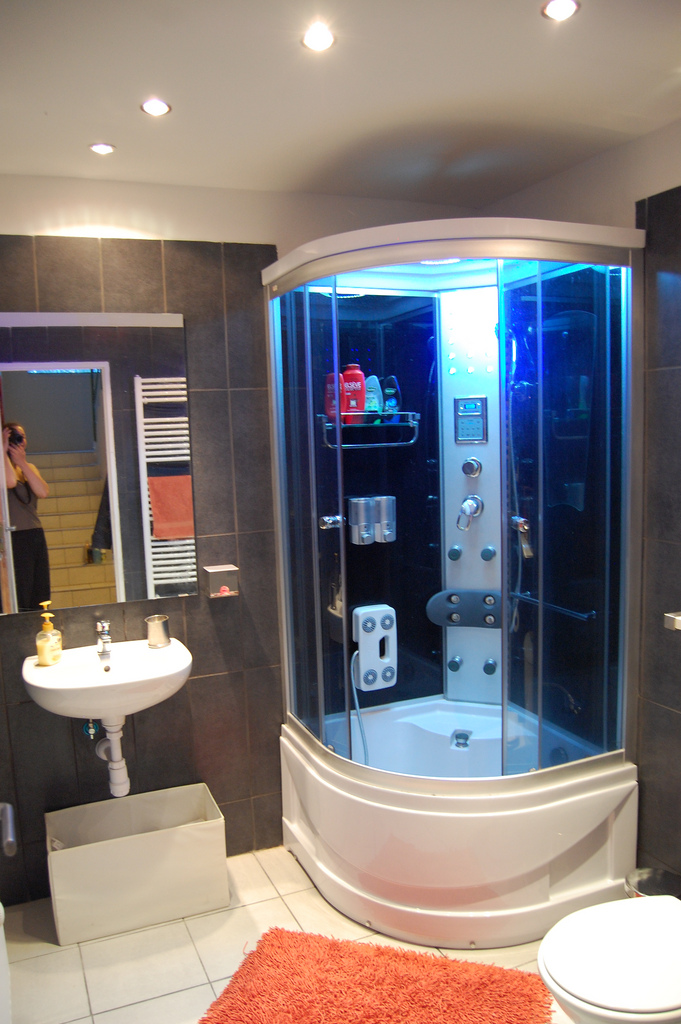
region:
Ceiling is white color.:
[16, 30, 572, 185]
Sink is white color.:
[18, 632, 206, 725]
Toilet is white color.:
[526, 892, 679, 1020]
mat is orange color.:
[206, 927, 536, 1022]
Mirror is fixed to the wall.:
[12, 352, 136, 618]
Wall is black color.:
[12, 252, 276, 857]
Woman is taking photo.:
[3, 423, 66, 612]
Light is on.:
[60, 13, 608, 180]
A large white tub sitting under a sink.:
[40, 781, 230, 950]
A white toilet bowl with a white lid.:
[534, 894, 677, 1022]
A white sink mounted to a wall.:
[20, 613, 197, 798]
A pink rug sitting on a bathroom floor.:
[195, 925, 555, 1022]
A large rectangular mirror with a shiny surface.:
[1, 355, 127, 620]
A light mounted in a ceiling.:
[138, 94, 174, 124]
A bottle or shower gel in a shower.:
[340, 355, 368, 420]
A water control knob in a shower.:
[455, 491, 484, 520]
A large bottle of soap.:
[30, 606, 68, 667]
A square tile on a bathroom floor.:
[80, 914, 212, 1013]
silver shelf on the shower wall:
[319, 407, 422, 448]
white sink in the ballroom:
[23, 610, 196, 796]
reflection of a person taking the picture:
[0, 423, 55, 610]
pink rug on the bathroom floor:
[198, 925, 548, 1022]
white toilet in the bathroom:
[535, 892, 679, 1022]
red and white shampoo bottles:
[322, 361, 366, 426]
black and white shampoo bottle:
[383, 375, 400, 418]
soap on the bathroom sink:
[33, 611, 64, 667]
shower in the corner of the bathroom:
[261, 214, 638, 950]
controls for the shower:
[453, 397, 488, 447]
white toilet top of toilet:
[542, 893, 678, 1014]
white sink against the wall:
[18, 634, 190, 719]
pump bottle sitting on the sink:
[29, 599, 66, 667]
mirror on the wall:
[0, 360, 126, 615]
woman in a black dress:
[1, 421, 52, 609]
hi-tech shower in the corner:
[260, 276, 652, 950]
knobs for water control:
[444, 537, 497, 564]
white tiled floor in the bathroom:
[3, 843, 576, 1022]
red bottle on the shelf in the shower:
[336, 359, 365, 424]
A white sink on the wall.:
[13, 620, 200, 744]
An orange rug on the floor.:
[230, 910, 551, 1021]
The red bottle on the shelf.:
[325, 355, 367, 422]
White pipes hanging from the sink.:
[97, 739, 147, 803]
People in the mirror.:
[5, 424, 73, 601]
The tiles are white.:
[29, 941, 266, 1022]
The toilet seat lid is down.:
[531, 889, 679, 994]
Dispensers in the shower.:
[339, 485, 408, 560]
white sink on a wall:
[22, 630, 194, 796]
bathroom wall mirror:
[3, 310, 199, 616]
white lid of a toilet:
[532, 890, 679, 1021]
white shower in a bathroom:
[257, 215, 653, 945]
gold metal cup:
[140, 610, 174, 651]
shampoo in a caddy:
[319, 361, 421, 448]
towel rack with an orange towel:
[132, 372, 204, 600]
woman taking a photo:
[1, 419, 58, 609]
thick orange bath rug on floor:
[197, 923, 556, 1021]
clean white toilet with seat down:
[535, 890, 679, 1021]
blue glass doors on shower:
[252, 232, 636, 783]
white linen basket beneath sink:
[41, 778, 232, 948]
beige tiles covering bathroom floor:
[0, 845, 580, 1022]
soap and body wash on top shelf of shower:
[324, 355, 402, 423]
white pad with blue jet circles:
[348, 602, 401, 694]